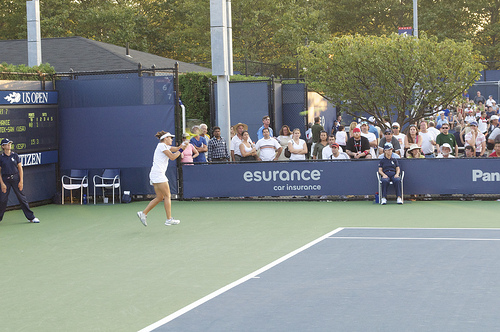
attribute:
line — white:
[167, 227, 350, 329]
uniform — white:
[147, 131, 179, 186]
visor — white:
[158, 126, 178, 144]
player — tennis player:
[134, 126, 195, 229]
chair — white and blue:
[55, 160, 93, 208]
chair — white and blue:
[91, 161, 124, 208]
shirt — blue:
[2, 148, 27, 175]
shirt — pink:
[180, 142, 195, 157]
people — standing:
[230, 118, 331, 155]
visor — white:
[160, 130, 175, 138]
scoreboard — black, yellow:
[3, 77, 78, 164]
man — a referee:
[377, 142, 405, 205]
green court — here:
[2, 202, 341, 329]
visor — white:
[155, 127, 175, 138]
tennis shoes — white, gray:
[134, 206, 184, 231]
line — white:
[215, 209, 320, 279]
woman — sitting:
[377, 142, 403, 204]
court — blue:
[2, 201, 499, 329]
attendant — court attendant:
[379, 142, 406, 204]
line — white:
[133, 224, 347, 330]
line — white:
[329, 233, 498, 249]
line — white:
[340, 216, 498, 236]